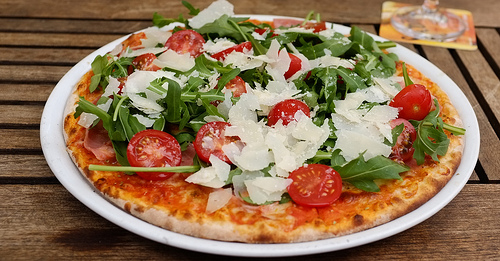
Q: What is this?
A: Veggie pizza.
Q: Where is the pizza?
A: On the plate.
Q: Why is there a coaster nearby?
A: Glass.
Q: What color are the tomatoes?
A: Red.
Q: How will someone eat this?
A: Knife and fork.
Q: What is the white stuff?
A: Onions.